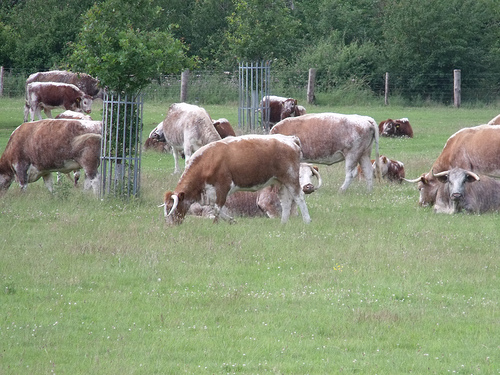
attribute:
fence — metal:
[99, 89, 144, 202]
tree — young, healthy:
[67, 21, 191, 205]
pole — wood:
[452, 69, 464, 108]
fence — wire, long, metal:
[145, 65, 500, 110]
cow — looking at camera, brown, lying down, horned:
[432, 126, 499, 199]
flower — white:
[309, 290, 314, 294]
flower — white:
[277, 264, 281, 269]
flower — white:
[267, 266, 271, 269]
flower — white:
[158, 277, 162, 283]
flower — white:
[193, 324, 196, 329]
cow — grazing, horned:
[157, 133, 314, 229]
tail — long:
[366, 117, 383, 184]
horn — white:
[169, 194, 178, 216]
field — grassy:
[1, 97, 500, 370]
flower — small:
[53, 320, 60, 327]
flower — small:
[31, 326, 36, 333]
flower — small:
[6, 325, 11, 330]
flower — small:
[73, 301, 78, 306]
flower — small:
[128, 328, 131, 333]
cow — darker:
[378, 117, 414, 138]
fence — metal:
[235, 60, 281, 133]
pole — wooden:
[180, 69, 189, 101]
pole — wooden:
[306, 67, 317, 103]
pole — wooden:
[385, 72, 393, 106]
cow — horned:
[199, 163, 324, 224]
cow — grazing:
[265, 112, 385, 191]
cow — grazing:
[0, 118, 104, 194]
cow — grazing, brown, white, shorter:
[25, 82, 93, 120]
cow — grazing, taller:
[25, 69, 104, 100]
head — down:
[158, 192, 192, 226]